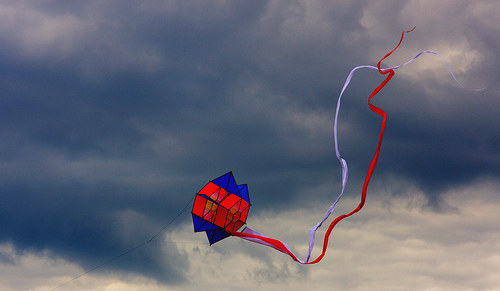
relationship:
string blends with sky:
[202, 232, 293, 288] [2, 4, 498, 286]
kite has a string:
[192, 28, 459, 271] [202, 232, 293, 288]